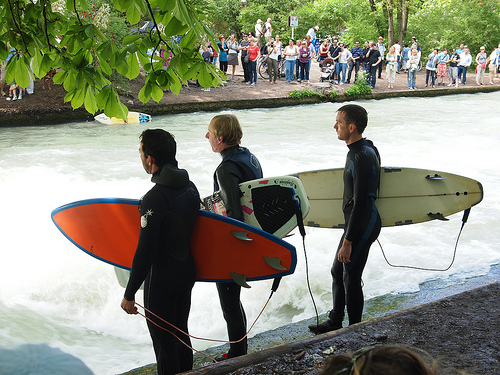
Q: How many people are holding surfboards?
A: 3.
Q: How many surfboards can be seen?
A: 4.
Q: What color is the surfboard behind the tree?
A: Yellow.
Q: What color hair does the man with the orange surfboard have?
A: Black.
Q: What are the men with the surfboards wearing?
A: Wet suits.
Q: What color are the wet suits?
A: Black.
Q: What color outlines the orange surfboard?
A: Blue.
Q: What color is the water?
A: White.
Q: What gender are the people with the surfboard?
A: Male.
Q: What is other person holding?
A: Surfboard.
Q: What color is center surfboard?
A: White and pink.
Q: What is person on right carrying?
A: Surfboard.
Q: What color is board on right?
A: White.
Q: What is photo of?
A: Three men ready to surf.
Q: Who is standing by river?
A: The people.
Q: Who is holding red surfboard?
A: Man on left.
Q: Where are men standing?
A: Side of the river.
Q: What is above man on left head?
A: Leaves.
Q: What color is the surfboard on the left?
A: Red and blue.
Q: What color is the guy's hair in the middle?
A: Blonde.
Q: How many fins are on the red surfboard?
A: 3.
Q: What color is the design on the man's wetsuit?
A: White.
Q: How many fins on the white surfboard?
A: 2.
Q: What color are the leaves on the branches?
A: Green.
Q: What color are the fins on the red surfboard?
A: Gray.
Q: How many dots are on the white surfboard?
A: 2.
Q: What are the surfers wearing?
A: Wetsuits.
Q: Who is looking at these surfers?
A: The photographer.